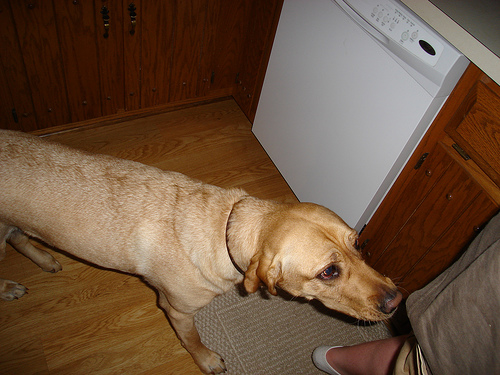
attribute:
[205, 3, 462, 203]
dishwasher — closed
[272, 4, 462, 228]
machine — white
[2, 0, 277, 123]
cabinets — wood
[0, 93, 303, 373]
flooring — wood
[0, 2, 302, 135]
door — kitchen cupboard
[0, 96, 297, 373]
floor — wood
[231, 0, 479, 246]
stove — white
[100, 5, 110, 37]
handle — metal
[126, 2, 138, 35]
handle — metal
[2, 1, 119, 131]
door — wooden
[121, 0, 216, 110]
door — wooden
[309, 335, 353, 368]
socks — short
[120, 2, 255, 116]
door — kitchen cupboard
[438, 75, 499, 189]
drawer — kitchen cabinet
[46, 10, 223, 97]
cabinets — brown wood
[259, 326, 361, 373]
shoes — white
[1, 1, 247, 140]
cabinets — wooden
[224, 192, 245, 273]
collar — brown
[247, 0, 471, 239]
dishwasher — white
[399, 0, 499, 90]
countertop — beige, off-white